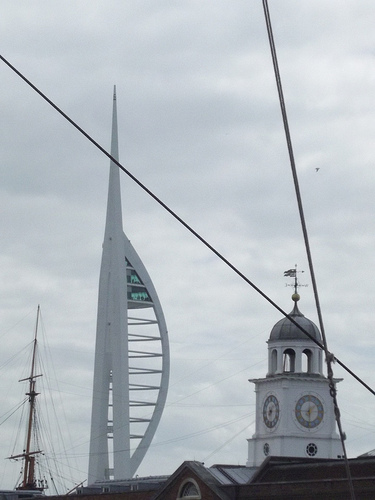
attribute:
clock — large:
[291, 390, 327, 430]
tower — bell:
[237, 255, 349, 466]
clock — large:
[257, 390, 283, 433]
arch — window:
[296, 345, 317, 376]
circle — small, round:
[302, 439, 319, 458]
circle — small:
[259, 440, 271, 458]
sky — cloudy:
[1, 2, 373, 497]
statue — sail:
[66, 78, 182, 490]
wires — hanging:
[1, 54, 374, 393]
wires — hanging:
[257, 3, 360, 500]